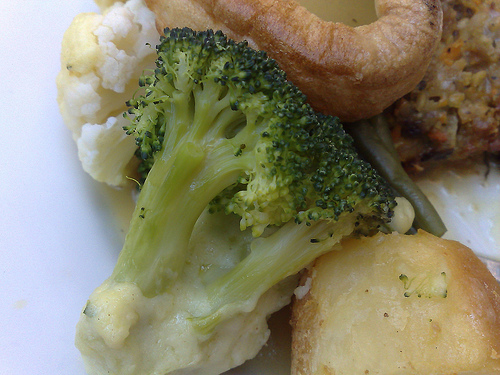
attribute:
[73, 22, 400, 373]
vegetable — part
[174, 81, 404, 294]
food — edge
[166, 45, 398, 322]
vegetable — edge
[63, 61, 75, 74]
speck — green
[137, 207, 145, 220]
green spot — dark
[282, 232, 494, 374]
food — part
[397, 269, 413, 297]
speck — green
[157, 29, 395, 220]
speckle — green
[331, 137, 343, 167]
speckle — green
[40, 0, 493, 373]
food — pile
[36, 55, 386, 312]
broccoli — pieced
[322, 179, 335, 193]
speckle — green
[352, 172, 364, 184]
speckle — green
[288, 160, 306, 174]
speckle — green